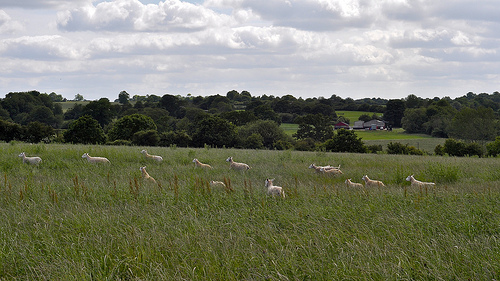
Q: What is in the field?
A: Animals.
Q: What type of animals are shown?
A: Sheep.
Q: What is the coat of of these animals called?
A: Wool.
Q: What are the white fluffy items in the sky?
A: Clouds.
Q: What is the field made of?
A: Grass.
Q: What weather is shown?
A: Cloudy.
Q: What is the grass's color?
A: Green.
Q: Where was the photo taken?
A: In a field.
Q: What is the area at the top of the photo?
A: The sky.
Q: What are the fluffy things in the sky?
A: Clouds.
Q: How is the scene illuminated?
A: With sunlight.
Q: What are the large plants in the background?
A: Trees.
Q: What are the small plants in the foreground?
A: Grass.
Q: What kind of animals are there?
A: Sheep.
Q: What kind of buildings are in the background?
A: Barns.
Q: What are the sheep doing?
A: Walking.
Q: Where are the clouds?
A: In the sky.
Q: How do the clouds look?
A: Gray and billowy.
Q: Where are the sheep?
A: In a field.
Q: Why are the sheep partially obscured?
A: Tall grass.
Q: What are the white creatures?
A: Sheep.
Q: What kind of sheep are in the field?
A: White.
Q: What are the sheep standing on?
A: A grassy hill.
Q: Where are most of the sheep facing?
A: Left.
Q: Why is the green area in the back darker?
A: Trees.